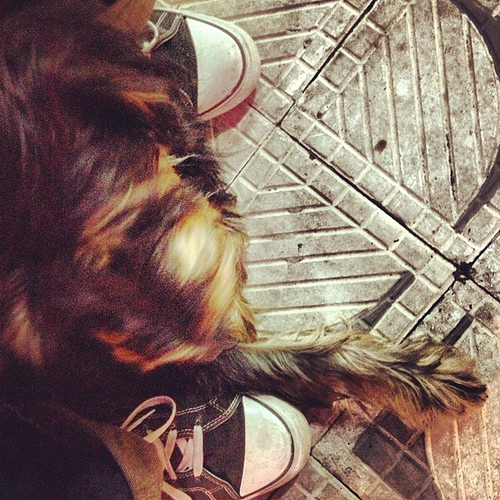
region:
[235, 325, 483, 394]
a brown dog's paw.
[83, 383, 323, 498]
a black and white shoe.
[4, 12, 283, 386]
a dog with brown hair.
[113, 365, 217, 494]
a white shoe lace in a shoe.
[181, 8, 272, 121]
the front half of a white shoe.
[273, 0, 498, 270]
a tile on the floor.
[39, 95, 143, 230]
a dark spot of fur.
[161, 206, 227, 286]
a section of brown fur.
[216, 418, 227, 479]
a section of a black shoe.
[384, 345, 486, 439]
a dog's paw.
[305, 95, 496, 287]
dirt on the ground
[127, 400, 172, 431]
a shoe lace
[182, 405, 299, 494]
black and white shoes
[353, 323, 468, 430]
a dogs paw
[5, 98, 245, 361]
a dog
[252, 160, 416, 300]
the tile is white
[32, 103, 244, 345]
the dog is on the ground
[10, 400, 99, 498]
blue jeans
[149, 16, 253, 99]
a person shoe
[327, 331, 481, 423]
dogs paw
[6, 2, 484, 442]
dog setting between a humans feet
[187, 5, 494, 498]
flooring covered in ornate tile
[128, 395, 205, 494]
white sneaker shoe lace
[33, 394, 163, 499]
cuff of blue jean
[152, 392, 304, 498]
black and white chuck sneaker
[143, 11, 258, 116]
black and white chuck sneaker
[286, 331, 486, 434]
right paw of a shaggy dog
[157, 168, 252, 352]
chest hair of a shaggy dog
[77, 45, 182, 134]
ear of a shaggy dog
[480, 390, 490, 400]
toenail of a shaggy dog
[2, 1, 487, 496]
dog laying between human's legs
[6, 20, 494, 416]
brown dog laying down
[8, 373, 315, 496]
person wear jeans and sneakers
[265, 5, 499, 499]
dirty white and black tile floor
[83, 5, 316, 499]
white and black sneakers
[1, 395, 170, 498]
jean leg with turned up cuff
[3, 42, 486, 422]
dog with leg exended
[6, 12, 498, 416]
multi colored dog coat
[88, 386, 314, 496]
shoe with white laces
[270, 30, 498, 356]
dingy floor tiles with dirt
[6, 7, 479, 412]
dog laying between two shoes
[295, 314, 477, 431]
paw of dog with long hair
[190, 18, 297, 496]
white toes of sneakers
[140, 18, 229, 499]
white laces on sneakers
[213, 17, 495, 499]
gray tile on floor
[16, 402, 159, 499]
pants leg of person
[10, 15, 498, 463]
dog laying on the floor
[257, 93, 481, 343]
black grout in tiles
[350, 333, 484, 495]
black arc on tiles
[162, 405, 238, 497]
white seams of shoe